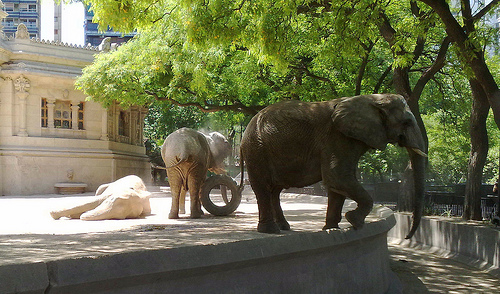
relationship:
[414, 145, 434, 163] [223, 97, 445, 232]
tusk of elephant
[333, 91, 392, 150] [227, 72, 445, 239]
ear of elephant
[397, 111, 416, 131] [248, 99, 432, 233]
eye on a elephant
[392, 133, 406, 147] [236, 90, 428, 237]
mouth of an elephant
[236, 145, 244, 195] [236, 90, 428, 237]
elephant tail of an elephant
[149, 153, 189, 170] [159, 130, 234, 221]
elephant tail of an elephant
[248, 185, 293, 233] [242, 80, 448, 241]
back legs of an elephant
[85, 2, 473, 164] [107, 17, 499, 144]
leaves on a tree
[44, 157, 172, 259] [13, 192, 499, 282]
elephant on ground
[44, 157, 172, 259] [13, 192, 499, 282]
elephant lying on ground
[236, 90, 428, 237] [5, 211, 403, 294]
elephant on ledge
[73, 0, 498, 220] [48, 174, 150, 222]
trees near elephant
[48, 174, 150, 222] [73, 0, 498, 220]
elephant near trees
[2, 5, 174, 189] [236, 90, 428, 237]
building behind elephant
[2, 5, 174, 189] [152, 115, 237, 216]
building behind elephant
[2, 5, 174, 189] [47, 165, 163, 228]
building behind elephant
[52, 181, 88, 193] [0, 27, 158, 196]
bench next to building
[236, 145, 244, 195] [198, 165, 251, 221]
elephant tail next to tire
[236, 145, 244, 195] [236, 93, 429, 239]
elephant tail of an elephant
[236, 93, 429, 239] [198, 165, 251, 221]
elephant next to tire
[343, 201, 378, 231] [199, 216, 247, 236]
foot raised from ground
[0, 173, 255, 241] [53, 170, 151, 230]
sunlight shines on an elephant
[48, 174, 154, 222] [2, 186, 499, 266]
elephant lying on floor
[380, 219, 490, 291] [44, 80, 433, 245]
walkway below elephants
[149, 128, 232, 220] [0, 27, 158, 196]
elephant in front of building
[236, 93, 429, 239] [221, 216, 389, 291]
elephant on platform